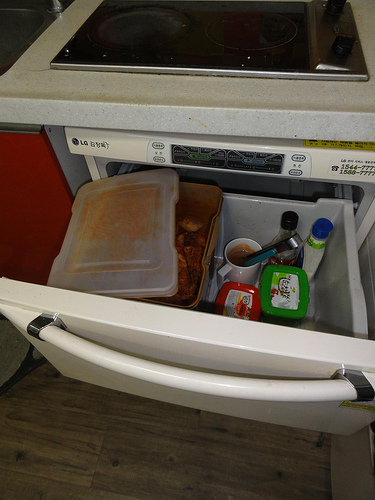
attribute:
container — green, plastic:
[261, 265, 308, 319]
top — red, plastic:
[215, 282, 260, 319]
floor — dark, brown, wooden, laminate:
[4, 355, 374, 500]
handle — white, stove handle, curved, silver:
[30, 312, 375, 403]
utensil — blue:
[237, 241, 286, 264]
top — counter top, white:
[2, 0, 373, 111]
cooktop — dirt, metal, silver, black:
[52, 0, 370, 80]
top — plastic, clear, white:
[48, 167, 179, 296]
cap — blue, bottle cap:
[312, 218, 332, 239]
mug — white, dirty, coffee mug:
[216, 238, 263, 283]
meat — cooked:
[182, 221, 203, 231]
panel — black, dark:
[170, 142, 286, 176]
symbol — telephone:
[331, 163, 340, 175]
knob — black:
[330, 32, 357, 58]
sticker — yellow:
[305, 137, 374, 153]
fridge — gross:
[3, 128, 374, 437]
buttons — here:
[285, 151, 314, 183]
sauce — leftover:
[77, 175, 162, 254]